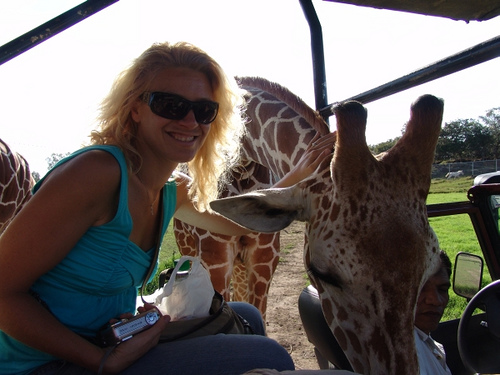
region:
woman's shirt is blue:
[34, 130, 220, 368]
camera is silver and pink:
[85, 295, 172, 351]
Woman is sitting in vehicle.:
[1, 2, 498, 374]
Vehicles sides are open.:
[1, 6, 498, 373]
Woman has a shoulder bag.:
[126, 180, 266, 357]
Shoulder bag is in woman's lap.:
[125, 172, 266, 349]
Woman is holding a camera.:
[103, 303, 166, 351]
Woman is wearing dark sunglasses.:
[126, 81, 221, 127]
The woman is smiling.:
[118, 56, 209, 153]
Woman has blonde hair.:
[83, 37, 255, 213]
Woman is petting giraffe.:
[156, 72, 448, 372]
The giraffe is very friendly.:
[169, 49, 461, 373]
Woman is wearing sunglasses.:
[123, 80, 225, 129]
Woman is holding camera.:
[106, 297, 173, 348]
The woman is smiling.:
[86, 37, 246, 216]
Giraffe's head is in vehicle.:
[131, 39, 468, 374]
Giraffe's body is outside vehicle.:
[121, 39, 295, 374]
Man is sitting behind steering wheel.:
[377, 240, 499, 372]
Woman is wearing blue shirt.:
[0, 135, 192, 373]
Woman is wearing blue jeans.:
[60, 285, 305, 374]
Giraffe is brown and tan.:
[168, 45, 461, 368]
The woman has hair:
[91, 32, 256, 213]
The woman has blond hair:
[77, 51, 269, 219]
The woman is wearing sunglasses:
[136, 81, 228, 133]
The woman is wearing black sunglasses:
[142, 75, 232, 135]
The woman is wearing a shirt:
[31, 168, 199, 353]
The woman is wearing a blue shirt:
[30, 115, 180, 340]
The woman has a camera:
[83, 299, 175, 344]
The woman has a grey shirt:
[100, 302, 166, 343]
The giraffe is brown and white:
[253, 112, 373, 273]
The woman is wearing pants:
[111, 301, 282, 373]